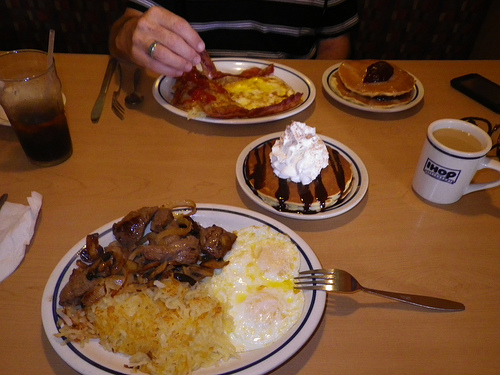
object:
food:
[83, 213, 299, 366]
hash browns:
[60, 272, 258, 373]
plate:
[321, 57, 426, 119]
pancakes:
[339, 58, 417, 97]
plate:
[233, 131, 369, 219]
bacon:
[173, 72, 230, 116]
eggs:
[216, 64, 299, 110]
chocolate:
[326, 146, 351, 201]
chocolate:
[313, 177, 328, 212]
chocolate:
[294, 181, 312, 212]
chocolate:
[274, 177, 290, 212]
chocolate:
[251, 145, 265, 195]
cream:
[268, 121, 329, 184]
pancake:
[227, 122, 370, 227]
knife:
[74, 51, 129, 131]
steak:
[56, 223, 236, 307]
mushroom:
[218, 230, 231, 249]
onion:
[156, 214, 192, 245]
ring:
[141, 37, 162, 61]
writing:
[422, 155, 461, 190]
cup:
[0, 45, 74, 168]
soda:
[15, 107, 76, 162]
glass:
[0, 47, 75, 167]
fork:
[292, 267, 467, 317]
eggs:
[164, 211, 374, 350]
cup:
[411, 114, 498, 208]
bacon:
[188, 41, 276, 85]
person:
[94, 5, 372, 68]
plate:
[150, 49, 315, 134]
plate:
[33, 202, 334, 372]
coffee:
[430, 127, 488, 154]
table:
[6, 47, 498, 368]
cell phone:
[446, 62, 498, 122]